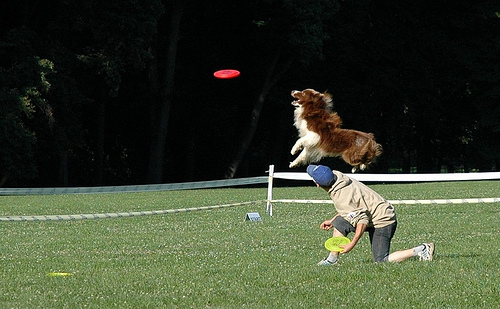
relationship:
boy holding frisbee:
[304, 155, 437, 267] [320, 232, 354, 253]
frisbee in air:
[209, 64, 245, 84] [2, 2, 494, 189]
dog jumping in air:
[289, 88, 383, 174] [2, 2, 494, 189]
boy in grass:
[304, 155, 437, 267] [0, 178, 498, 305]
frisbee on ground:
[45, 265, 68, 275] [3, 176, 496, 305]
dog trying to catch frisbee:
[280, 85, 390, 169] [210, 65, 245, 85]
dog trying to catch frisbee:
[280, 85, 390, 169] [209, 65, 245, 89]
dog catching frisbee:
[280, 85, 390, 169] [210, 65, 245, 85]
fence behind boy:
[0, 171, 499, 221] [305, 165, 436, 268]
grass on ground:
[0, 178, 498, 305] [3, 176, 496, 305]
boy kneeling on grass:
[305, 165, 436, 268] [0, 178, 498, 305]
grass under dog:
[0, 178, 498, 305] [289, 88, 383, 174]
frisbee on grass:
[49, 272, 70, 277] [0, 178, 498, 305]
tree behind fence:
[3, 6, 494, 184] [0, 171, 499, 221]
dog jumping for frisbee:
[289, 88, 383, 174] [212, 69, 242, 79]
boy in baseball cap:
[305, 165, 436, 268] [304, 165, 335, 188]